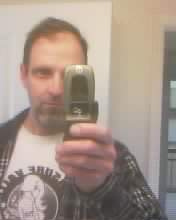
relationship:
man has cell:
[6, 22, 151, 219] [54, 67, 95, 153]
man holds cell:
[6, 22, 151, 219] [61, 66, 95, 153]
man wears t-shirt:
[6, 22, 151, 219] [7, 131, 65, 217]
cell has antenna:
[61, 66, 95, 153] [92, 101, 103, 118]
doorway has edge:
[153, 31, 175, 212] [161, 39, 173, 157]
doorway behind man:
[153, 31, 175, 212] [6, 22, 151, 219]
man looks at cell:
[6, 22, 151, 219] [54, 67, 95, 153]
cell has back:
[54, 67, 95, 153] [66, 74, 91, 122]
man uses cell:
[6, 22, 151, 219] [54, 67, 95, 153]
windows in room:
[167, 80, 175, 116] [164, 76, 176, 190]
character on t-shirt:
[19, 166, 43, 219] [7, 131, 65, 217]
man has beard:
[6, 22, 151, 219] [31, 91, 65, 126]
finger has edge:
[68, 113, 120, 143] [82, 121, 107, 128]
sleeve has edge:
[68, 189, 151, 219] [86, 172, 115, 196]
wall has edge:
[104, 1, 167, 163] [161, 39, 173, 157]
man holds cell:
[6, 22, 151, 219] [54, 67, 95, 153]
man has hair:
[6, 22, 151, 219] [18, 10, 96, 60]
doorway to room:
[153, 31, 175, 212] [155, 20, 172, 219]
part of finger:
[98, 127, 110, 137] [68, 113, 120, 143]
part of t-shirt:
[2, 163, 65, 218] [7, 131, 65, 217]